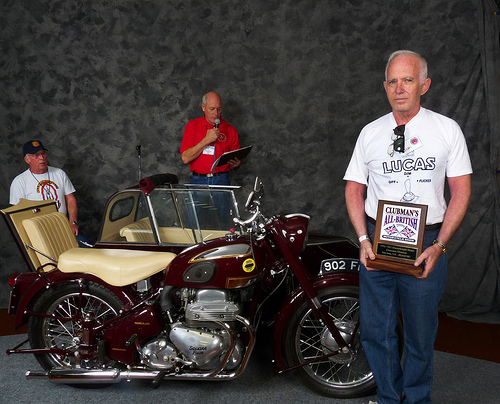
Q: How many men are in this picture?
A: Three.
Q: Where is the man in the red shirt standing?
A: Behind the motorcycle.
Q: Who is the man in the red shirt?
A: The auctioneer.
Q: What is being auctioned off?
A: A motorcycle.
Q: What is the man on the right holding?
A: A plaque.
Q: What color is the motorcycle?
A: Brown.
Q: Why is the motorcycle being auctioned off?
A: It is for sell.